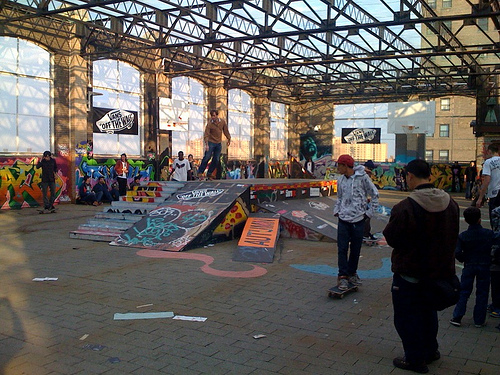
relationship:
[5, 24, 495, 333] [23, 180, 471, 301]
indoor an park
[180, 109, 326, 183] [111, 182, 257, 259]
skateboarding on ramp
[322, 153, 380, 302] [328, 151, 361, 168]
boy with hat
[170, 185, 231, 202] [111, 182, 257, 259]
grafitti on ramp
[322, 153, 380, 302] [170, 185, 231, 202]
boy in front of grafitti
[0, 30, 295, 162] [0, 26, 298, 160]
windows in row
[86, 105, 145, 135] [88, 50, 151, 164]
sign in window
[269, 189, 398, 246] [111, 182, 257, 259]
black orange ramp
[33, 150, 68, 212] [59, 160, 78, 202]
someone's arm shadow's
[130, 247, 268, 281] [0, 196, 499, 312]
shape on floor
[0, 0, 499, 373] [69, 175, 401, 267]
warehouse converted park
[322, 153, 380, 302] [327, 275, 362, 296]
boy on skateboard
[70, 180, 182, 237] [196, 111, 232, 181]
jumps for person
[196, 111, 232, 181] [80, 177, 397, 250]
person using ramps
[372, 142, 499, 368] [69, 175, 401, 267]
spectators of park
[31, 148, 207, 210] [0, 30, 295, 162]
spectators under windows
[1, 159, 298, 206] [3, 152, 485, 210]
graffiti along walls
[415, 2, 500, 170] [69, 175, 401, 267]
building behind park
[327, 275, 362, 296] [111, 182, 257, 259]
skateboard a ramp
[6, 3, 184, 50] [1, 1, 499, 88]
metal black rafters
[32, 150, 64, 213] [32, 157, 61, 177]
man in coat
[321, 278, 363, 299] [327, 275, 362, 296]
grey a skateboard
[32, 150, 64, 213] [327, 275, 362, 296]
man on skateboard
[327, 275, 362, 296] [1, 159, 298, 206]
skateboard with graffiti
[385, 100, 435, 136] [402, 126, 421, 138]
basket ball net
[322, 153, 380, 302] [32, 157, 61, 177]
boy in coat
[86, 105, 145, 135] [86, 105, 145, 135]
sign with sign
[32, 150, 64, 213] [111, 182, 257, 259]
man on ramp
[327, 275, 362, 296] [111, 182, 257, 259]
skateboard black ramp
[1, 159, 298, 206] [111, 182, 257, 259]
graffiti on ramp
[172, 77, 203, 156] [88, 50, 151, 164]
glass pane window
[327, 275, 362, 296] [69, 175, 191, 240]
skateboard cement steps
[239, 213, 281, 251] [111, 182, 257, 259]
sign on ramp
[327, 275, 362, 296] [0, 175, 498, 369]
skateboard on ground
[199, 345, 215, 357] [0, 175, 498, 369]
brick brown ground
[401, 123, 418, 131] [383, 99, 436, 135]
hoop attached to backboard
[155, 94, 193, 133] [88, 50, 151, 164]
banner on window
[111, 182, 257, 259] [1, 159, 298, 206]
ramp with graffiti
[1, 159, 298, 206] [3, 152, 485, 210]
graffiti covering walls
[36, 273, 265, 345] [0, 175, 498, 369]
litter on ground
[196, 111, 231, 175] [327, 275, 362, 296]
person on skateboard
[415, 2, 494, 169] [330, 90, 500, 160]
building in background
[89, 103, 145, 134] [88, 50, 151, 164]
advertisement on window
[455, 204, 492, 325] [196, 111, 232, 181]
child watcihng person